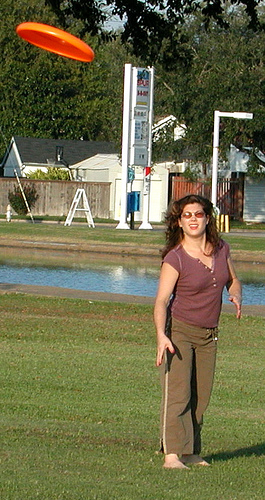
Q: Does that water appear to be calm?
A: Yes, the water is calm.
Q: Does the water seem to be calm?
A: Yes, the water is calm.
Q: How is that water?
A: The water is calm.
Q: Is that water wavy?
A: No, the water is calm.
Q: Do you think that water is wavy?
A: No, the water is calm.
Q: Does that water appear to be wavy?
A: No, the water is calm.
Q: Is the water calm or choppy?
A: The water is calm.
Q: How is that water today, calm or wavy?
A: The water is calm.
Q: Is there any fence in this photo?
A: Yes, there is a fence.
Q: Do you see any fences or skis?
A: Yes, there is a fence.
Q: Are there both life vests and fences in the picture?
A: No, there is a fence but no life jackets.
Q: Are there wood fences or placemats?
A: Yes, there is a wood fence.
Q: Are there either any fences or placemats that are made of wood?
A: Yes, the fence is made of wood.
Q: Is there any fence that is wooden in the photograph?
A: Yes, there is a wood fence.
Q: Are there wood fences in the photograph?
A: Yes, there is a wood fence.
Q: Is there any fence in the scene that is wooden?
A: Yes, there is a fence that is wooden.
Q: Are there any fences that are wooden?
A: Yes, there is a fence that is wooden.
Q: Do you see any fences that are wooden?
A: Yes, there is a fence that is wooden.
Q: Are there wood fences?
A: Yes, there is a fence that is made of wood.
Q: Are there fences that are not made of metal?
A: Yes, there is a fence that is made of wood.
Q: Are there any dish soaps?
A: No, there are no dish soaps.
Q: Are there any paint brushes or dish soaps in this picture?
A: No, there are no dish soaps or paint brushes.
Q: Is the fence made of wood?
A: Yes, the fence is made of wood.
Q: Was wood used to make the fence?
A: Yes, the fence is made of wood.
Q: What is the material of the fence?
A: The fence is made of wood.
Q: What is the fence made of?
A: The fence is made of wood.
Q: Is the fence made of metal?
A: No, the fence is made of wood.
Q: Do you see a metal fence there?
A: No, there is a fence but it is made of wood.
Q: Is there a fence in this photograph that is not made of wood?
A: No, there is a fence but it is made of wood.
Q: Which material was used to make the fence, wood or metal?
A: The fence is made of wood.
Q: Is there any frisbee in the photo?
A: Yes, there is a frisbee.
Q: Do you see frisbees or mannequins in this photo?
A: Yes, there is a frisbee.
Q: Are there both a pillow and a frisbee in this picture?
A: No, there is a frisbee but no pillows.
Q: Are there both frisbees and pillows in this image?
A: No, there is a frisbee but no pillows.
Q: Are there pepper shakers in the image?
A: No, there are no pepper shakers.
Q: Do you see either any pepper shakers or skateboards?
A: No, there are no pepper shakers or skateboards.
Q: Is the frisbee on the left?
A: Yes, the frisbee is on the left of the image.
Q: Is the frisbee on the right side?
A: No, the frisbee is on the left of the image.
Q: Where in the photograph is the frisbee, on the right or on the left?
A: The frisbee is on the left of the image.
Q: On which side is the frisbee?
A: The frisbee is on the left of the image.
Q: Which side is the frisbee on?
A: The frisbee is on the left of the image.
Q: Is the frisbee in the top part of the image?
A: Yes, the frisbee is in the top of the image.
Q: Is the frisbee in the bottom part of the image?
A: No, the frisbee is in the top of the image.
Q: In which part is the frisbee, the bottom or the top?
A: The frisbee is in the top of the image.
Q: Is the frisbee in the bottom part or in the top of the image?
A: The frisbee is in the top of the image.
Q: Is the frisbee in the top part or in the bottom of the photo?
A: The frisbee is in the top of the image.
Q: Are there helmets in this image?
A: No, there are no helmets.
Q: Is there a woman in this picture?
A: Yes, there is a woman.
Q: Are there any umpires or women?
A: Yes, there is a woman.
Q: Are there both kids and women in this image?
A: No, there is a woman but no children.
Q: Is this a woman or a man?
A: This is a woman.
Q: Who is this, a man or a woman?
A: This is a woman.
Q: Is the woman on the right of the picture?
A: Yes, the woman is on the right of the image.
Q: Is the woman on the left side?
A: No, the woman is on the right of the image.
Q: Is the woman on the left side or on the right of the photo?
A: The woman is on the right of the image.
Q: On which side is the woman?
A: The woman is on the right of the image.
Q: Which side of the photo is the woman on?
A: The woman is on the right of the image.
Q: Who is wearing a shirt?
A: The woman is wearing a shirt.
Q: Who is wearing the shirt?
A: The woman is wearing a shirt.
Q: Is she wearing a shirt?
A: Yes, the woman is wearing a shirt.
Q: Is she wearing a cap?
A: No, the woman is wearing a shirt.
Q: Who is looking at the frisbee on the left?
A: The woman is looking at the frisbee.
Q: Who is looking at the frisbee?
A: The woman is looking at the frisbee.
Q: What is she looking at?
A: The woman is looking at the frisbee.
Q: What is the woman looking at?
A: The woman is looking at the frisbee.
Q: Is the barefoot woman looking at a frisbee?
A: Yes, the woman is looking at a frisbee.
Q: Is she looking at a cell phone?
A: No, the woman is looking at a frisbee.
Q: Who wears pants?
A: The woman wears pants.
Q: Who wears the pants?
A: The woman wears pants.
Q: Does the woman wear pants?
A: Yes, the woman wears pants.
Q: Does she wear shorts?
A: No, the woman wears pants.